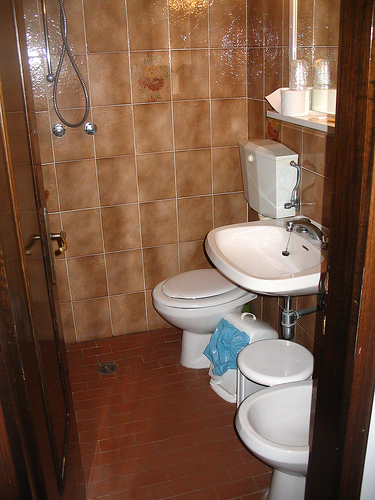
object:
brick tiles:
[93, 364, 188, 465]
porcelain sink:
[202, 211, 323, 295]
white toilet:
[149, 265, 262, 375]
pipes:
[281, 298, 301, 334]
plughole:
[98, 360, 117, 376]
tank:
[236, 141, 298, 212]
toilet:
[150, 259, 260, 371]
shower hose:
[37, 8, 104, 131]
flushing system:
[237, 137, 299, 217]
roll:
[267, 84, 309, 117]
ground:
[209, 88, 254, 133]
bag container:
[201, 318, 243, 404]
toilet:
[233, 378, 314, 498]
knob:
[52, 124, 66, 140]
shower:
[23, 0, 245, 465]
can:
[208, 310, 276, 406]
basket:
[205, 308, 281, 407]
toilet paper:
[275, 80, 307, 115]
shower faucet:
[37, 1, 98, 139]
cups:
[285, 56, 312, 94]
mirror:
[281, 2, 335, 115]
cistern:
[237, 136, 301, 218]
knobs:
[81, 121, 98, 141]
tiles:
[75, 167, 143, 249]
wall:
[29, 15, 306, 433]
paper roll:
[272, 84, 313, 115]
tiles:
[24, 2, 247, 224]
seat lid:
[161, 256, 227, 306]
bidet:
[231, 378, 313, 498]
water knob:
[85, 117, 100, 139]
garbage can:
[208, 310, 279, 398]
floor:
[65, 320, 294, 498]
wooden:
[0, 0, 57, 449]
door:
[0, 23, 69, 500]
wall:
[115, 34, 202, 170]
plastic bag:
[202, 319, 250, 378]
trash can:
[207, 312, 278, 405]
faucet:
[282, 217, 332, 245]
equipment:
[240, 339, 313, 380]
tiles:
[87, 373, 180, 452]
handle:
[46, 217, 76, 270]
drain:
[92, 358, 124, 378]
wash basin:
[211, 212, 330, 311]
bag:
[203, 320, 249, 382]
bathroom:
[2, 2, 374, 492]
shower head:
[46, 69, 58, 83]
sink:
[205, 207, 323, 307]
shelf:
[263, 98, 333, 137]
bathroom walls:
[7, 2, 324, 341]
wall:
[249, 6, 340, 363]